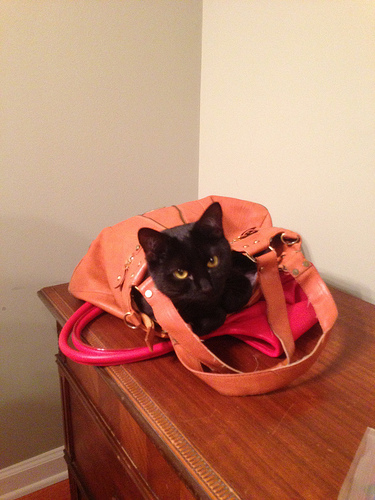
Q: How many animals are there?
A: 1.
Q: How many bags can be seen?
A: 2.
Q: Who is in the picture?
A: No one.